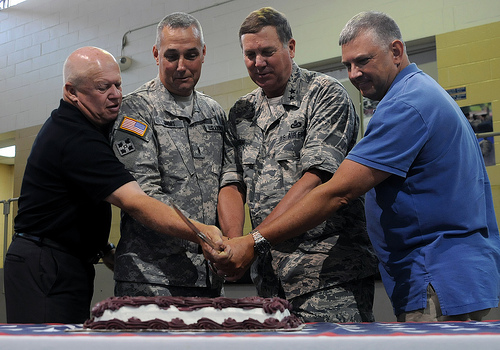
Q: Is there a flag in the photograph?
A: Yes, there is a flag.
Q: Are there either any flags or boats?
A: Yes, there is a flag.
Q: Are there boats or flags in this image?
A: Yes, there is a flag.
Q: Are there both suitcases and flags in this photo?
A: No, there is a flag but no suitcases.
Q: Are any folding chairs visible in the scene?
A: No, there are no folding chairs.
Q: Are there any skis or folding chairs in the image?
A: No, there are no folding chairs or skis.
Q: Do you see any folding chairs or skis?
A: No, there are no folding chairs or skis.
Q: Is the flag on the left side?
A: Yes, the flag is on the left of the image.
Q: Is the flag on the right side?
A: No, the flag is on the left of the image.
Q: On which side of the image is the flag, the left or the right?
A: The flag is on the left of the image.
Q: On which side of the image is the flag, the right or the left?
A: The flag is on the left of the image.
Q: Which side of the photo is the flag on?
A: The flag is on the left of the image.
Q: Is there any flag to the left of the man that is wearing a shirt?
A: Yes, there is a flag to the left of the man.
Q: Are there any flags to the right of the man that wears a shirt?
A: No, the flag is to the left of the man.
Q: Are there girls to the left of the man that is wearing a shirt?
A: No, there is a flag to the left of the man.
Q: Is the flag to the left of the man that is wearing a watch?
A: Yes, the flag is to the left of the man.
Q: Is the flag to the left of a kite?
A: No, the flag is to the left of the man.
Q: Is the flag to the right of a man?
A: No, the flag is to the left of a man.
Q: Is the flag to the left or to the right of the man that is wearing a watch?
A: The flag is to the left of the man.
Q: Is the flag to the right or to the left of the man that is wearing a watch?
A: The flag is to the left of the man.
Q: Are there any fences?
A: No, there are no fences.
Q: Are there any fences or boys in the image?
A: No, there are no fences or boys.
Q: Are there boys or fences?
A: No, there are no fences or boys.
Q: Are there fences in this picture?
A: No, there are no fences.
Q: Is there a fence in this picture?
A: No, there are no fences.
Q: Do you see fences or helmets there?
A: No, there are no fences or helmets.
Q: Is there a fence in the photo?
A: No, there are no fences.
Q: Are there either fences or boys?
A: No, there are no fences or boys.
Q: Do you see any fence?
A: No, there are no fences.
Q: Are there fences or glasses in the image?
A: No, there are no fences or glasses.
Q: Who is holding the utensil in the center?
A: The man is holding the knife.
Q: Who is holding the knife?
A: The man is holding the knife.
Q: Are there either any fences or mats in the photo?
A: No, there are no fences or mats.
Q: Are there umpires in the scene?
A: No, there are no umpires.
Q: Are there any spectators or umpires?
A: No, there are no umpires or spectators.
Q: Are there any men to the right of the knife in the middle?
A: Yes, there is a man to the right of the knife.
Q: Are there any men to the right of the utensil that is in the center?
A: Yes, there is a man to the right of the knife.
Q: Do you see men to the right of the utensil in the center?
A: Yes, there is a man to the right of the knife.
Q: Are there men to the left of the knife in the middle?
A: No, the man is to the right of the knife.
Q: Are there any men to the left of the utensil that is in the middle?
A: No, the man is to the right of the knife.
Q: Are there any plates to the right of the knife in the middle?
A: No, there is a man to the right of the knife.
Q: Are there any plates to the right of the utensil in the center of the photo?
A: No, there is a man to the right of the knife.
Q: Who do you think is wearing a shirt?
A: The man is wearing a shirt.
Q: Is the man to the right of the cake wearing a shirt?
A: Yes, the man is wearing a shirt.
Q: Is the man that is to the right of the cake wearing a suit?
A: No, the man is wearing a shirt.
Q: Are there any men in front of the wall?
A: Yes, there is a man in front of the wall.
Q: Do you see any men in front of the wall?
A: Yes, there is a man in front of the wall.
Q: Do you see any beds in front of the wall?
A: No, there is a man in front of the wall.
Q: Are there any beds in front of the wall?
A: No, there is a man in front of the wall.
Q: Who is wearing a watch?
A: The man is wearing a watch.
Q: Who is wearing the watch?
A: The man is wearing a watch.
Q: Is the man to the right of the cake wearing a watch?
A: Yes, the man is wearing a watch.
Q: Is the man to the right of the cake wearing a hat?
A: No, the man is wearing a watch.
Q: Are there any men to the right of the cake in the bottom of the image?
A: Yes, there is a man to the right of the cake.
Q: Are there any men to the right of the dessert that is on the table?
A: Yes, there is a man to the right of the cake.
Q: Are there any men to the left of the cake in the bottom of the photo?
A: No, the man is to the right of the cake.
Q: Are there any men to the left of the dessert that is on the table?
A: No, the man is to the right of the cake.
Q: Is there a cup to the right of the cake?
A: No, there is a man to the right of the cake.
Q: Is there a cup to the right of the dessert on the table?
A: No, there is a man to the right of the cake.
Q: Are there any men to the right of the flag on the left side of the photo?
A: Yes, there is a man to the right of the flag.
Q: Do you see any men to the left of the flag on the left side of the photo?
A: No, the man is to the right of the flag.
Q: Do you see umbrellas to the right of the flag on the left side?
A: No, there is a man to the right of the flag.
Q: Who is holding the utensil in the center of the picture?
A: The man is holding the knife.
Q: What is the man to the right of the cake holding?
A: The man is holding the knife.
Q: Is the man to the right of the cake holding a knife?
A: Yes, the man is holding a knife.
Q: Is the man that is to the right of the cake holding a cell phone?
A: No, the man is holding a knife.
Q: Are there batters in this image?
A: No, there are no batters.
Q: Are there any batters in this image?
A: No, there are no batters.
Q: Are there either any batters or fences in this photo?
A: No, there are no batters or fences.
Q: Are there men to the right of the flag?
A: Yes, there is a man to the right of the flag.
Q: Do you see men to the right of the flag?
A: Yes, there is a man to the right of the flag.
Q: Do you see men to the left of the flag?
A: No, the man is to the right of the flag.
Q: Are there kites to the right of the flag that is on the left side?
A: No, there is a man to the right of the flag.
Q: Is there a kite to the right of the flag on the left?
A: No, there is a man to the right of the flag.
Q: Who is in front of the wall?
A: The man is in front of the wall.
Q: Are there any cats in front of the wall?
A: No, there is a man in front of the wall.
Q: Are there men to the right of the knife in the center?
A: Yes, there is a man to the right of the knife.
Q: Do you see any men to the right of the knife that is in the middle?
A: Yes, there is a man to the right of the knife.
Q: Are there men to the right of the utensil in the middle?
A: Yes, there is a man to the right of the knife.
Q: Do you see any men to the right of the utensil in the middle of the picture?
A: Yes, there is a man to the right of the knife.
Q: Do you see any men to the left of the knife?
A: No, the man is to the right of the knife.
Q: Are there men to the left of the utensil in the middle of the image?
A: No, the man is to the right of the knife.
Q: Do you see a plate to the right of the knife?
A: No, there is a man to the right of the knife.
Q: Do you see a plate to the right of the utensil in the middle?
A: No, there is a man to the right of the knife.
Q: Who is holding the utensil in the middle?
A: The man is holding the knife.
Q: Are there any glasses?
A: No, there are no glasses.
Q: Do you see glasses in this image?
A: No, there are no glasses.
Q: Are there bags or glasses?
A: No, there are no glasses or bags.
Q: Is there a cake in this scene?
A: Yes, there is a cake.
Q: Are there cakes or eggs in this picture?
A: Yes, there is a cake.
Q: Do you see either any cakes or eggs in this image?
A: Yes, there is a cake.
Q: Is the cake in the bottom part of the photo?
A: Yes, the cake is in the bottom of the image.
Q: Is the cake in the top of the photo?
A: No, the cake is in the bottom of the image.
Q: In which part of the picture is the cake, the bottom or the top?
A: The cake is in the bottom of the image.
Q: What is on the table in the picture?
A: The cake is on the table.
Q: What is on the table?
A: The cake is on the table.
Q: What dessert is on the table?
A: The dessert is a cake.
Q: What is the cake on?
A: The cake is on the table.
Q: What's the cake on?
A: The cake is on the table.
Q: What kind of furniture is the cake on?
A: The cake is on the table.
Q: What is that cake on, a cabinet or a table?
A: The cake is on a table.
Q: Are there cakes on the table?
A: Yes, there is a cake on the table.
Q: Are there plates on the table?
A: No, there is a cake on the table.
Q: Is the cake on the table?
A: Yes, the cake is on the table.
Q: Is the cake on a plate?
A: No, the cake is on the table.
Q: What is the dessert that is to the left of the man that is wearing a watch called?
A: The dessert is a cake.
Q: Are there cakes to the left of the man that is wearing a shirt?
A: Yes, there is a cake to the left of the man.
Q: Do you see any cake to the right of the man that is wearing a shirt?
A: No, the cake is to the left of the man.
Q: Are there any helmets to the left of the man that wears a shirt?
A: No, there is a cake to the left of the man.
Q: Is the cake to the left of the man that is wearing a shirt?
A: Yes, the cake is to the left of the man.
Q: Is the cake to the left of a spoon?
A: No, the cake is to the left of the man.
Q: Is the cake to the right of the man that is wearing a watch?
A: No, the cake is to the left of the man.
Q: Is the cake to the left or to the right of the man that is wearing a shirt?
A: The cake is to the left of the man.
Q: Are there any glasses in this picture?
A: No, there are no glasses.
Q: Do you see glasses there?
A: No, there are no glasses.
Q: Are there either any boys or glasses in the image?
A: No, there are no glasses or boys.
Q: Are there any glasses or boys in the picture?
A: No, there are no glasses or boys.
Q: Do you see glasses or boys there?
A: No, there are no glasses or boys.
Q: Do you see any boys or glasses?
A: No, there are no glasses or boys.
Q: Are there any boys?
A: No, there are no boys.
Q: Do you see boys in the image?
A: No, there are no boys.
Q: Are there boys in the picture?
A: No, there are no boys.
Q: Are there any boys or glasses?
A: No, there are no boys or glasses.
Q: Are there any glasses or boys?
A: No, there are no boys or glasses.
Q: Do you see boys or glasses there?
A: No, there are no boys or glasses.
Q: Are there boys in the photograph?
A: No, there are no boys.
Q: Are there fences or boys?
A: No, there are no boys or fences.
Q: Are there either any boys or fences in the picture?
A: No, there are no boys or fences.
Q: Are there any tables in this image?
A: Yes, there is a table.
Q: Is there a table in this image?
A: Yes, there is a table.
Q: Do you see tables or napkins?
A: Yes, there is a table.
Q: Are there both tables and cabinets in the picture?
A: No, there is a table but no cabinets.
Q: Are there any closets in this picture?
A: No, there are no closets.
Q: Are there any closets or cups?
A: No, there are no closets or cups.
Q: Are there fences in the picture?
A: No, there are no fences.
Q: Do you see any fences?
A: No, there are no fences.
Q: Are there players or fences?
A: No, there are no fences or players.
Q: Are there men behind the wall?
A: No, the man is in front of the wall.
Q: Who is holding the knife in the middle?
A: The man is holding the knife.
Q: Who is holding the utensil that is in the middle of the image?
A: The man is holding the knife.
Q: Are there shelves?
A: No, there are no shelves.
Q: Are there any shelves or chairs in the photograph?
A: No, there are no shelves or chairs.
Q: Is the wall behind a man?
A: Yes, the wall is behind a man.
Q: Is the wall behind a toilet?
A: No, the wall is behind a man.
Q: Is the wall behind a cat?
A: No, the wall is behind a man.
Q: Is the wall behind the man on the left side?
A: Yes, the wall is behind the man.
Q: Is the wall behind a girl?
A: No, the wall is behind the man.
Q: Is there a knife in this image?
A: Yes, there is a knife.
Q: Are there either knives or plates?
A: Yes, there is a knife.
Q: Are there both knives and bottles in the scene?
A: No, there is a knife but no bottles.